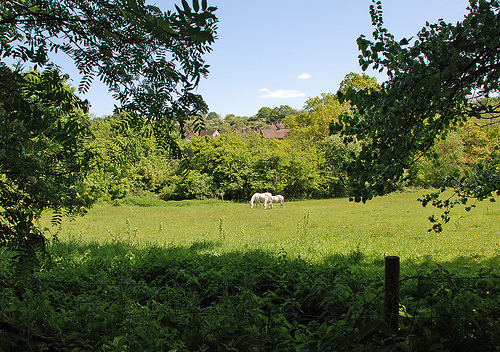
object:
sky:
[0, 1, 499, 119]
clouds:
[257, 87, 305, 100]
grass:
[40, 188, 498, 262]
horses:
[261, 194, 284, 210]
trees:
[0, 71, 500, 206]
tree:
[2, 0, 220, 280]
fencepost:
[384, 255, 401, 332]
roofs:
[178, 122, 289, 139]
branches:
[328, 0, 499, 234]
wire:
[0, 275, 499, 287]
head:
[246, 201, 254, 209]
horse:
[249, 192, 272, 209]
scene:
[1, 0, 493, 350]